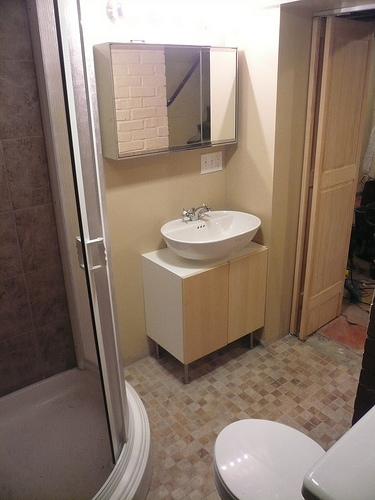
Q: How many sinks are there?
A: One.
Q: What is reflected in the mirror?
A: Brick.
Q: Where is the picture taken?
A: Bathroom.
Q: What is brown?
A: Door.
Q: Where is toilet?
A: Bottom right corner.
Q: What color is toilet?
A: White.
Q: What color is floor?
A: Brown.